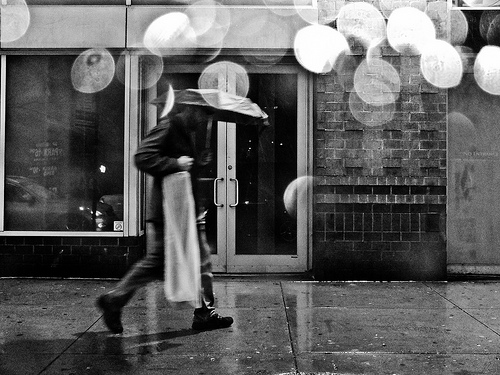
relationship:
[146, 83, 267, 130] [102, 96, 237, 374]
umbrella above man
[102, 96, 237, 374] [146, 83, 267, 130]
man below umbrella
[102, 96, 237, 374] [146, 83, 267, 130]
man under umbrella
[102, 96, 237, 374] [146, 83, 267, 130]
man has umbrella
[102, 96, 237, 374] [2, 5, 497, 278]
man beside building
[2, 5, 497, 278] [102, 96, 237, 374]
building beside man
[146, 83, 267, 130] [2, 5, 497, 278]
umbrella near building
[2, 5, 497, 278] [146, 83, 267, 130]
building near umbrella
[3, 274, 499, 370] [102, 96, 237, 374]
floor near man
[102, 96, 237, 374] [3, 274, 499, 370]
man near floor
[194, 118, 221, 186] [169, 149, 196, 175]
pole in hand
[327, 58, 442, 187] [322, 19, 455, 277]
bricks in wall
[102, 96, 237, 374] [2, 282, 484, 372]
man walking on sidewalk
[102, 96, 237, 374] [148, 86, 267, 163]
man holding umbrella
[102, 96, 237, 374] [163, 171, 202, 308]
man holding bag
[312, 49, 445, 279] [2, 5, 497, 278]
wall on building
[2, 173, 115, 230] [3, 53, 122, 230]
reflection in window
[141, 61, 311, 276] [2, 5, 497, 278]
doors on building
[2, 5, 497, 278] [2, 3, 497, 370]
building walking in rain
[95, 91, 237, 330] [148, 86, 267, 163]
man holding umbrella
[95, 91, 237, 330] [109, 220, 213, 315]
man wearing pants